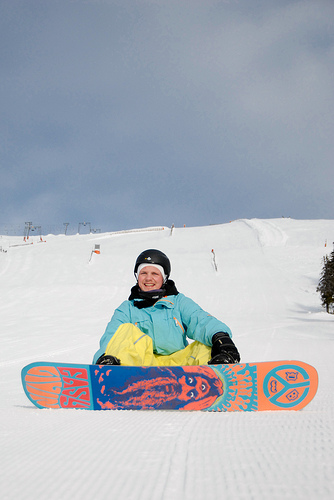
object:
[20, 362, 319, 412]
snowboard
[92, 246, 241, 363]
man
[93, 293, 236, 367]
coat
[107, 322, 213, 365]
snowpants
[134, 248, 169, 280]
helmet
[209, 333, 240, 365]
glove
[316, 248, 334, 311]
tree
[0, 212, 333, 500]
hillside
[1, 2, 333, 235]
sky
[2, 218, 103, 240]
lift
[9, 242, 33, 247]
skis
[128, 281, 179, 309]
muffler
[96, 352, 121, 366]
boots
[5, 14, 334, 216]
clouds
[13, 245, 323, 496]
snow